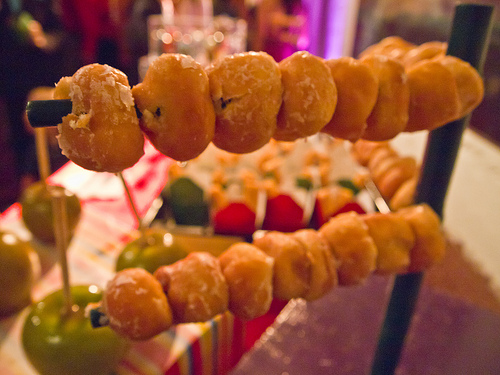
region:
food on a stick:
[21, 50, 493, 172]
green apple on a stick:
[15, 192, 146, 373]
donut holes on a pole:
[82, 207, 457, 352]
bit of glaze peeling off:
[111, 270, 141, 288]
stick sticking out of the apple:
[35, 134, 58, 189]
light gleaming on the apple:
[82, 281, 105, 294]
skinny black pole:
[357, 6, 499, 371]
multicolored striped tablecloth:
[2, 202, 235, 372]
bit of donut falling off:
[64, 107, 96, 138]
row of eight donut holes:
[33, 49, 482, 181]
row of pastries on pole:
[27, 47, 475, 167]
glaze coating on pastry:
[88, 80, 134, 141]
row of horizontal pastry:
[197, 228, 397, 315]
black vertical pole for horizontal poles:
[379, 33, 492, 327]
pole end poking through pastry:
[22, 78, 87, 141]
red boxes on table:
[213, 173, 320, 234]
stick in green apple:
[26, 216, 113, 363]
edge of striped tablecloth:
[185, 317, 253, 373]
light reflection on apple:
[155, 227, 177, 253]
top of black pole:
[445, 1, 497, 40]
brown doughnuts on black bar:
[49, 48, 494, 168]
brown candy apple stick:
[40, 195, 78, 290]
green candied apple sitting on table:
[30, 283, 110, 368]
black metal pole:
[420, 129, 467, 205]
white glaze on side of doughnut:
[101, 74, 136, 116]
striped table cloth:
[175, 323, 220, 362]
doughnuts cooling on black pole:
[41, 25, 481, 335]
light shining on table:
[89, 176, 122, 216]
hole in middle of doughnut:
[215, 82, 244, 121]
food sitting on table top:
[159, 156, 361, 225]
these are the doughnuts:
[71, 26, 466, 161]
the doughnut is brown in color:
[218, 53, 278, 134]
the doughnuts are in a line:
[73, 55, 383, 146]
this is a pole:
[423, 128, 461, 200]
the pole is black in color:
[413, 136, 465, 201]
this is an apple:
[31, 307, 83, 362]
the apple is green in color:
[37, 326, 90, 361]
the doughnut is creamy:
[70, 63, 127, 165]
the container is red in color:
[265, 197, 300, 227]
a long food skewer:
[30, 42, 495, 154]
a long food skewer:
[80, 202, 458, 344]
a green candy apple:
[19, 189, 131, 374]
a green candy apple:
[110, 177, 182, 277]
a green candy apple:
[23, 123, 81, 245]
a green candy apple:
[0, 232, 39, 312]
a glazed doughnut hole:
[48, 59, 138, 175]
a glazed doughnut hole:
[127, 44, 213, 161]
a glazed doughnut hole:
[213, 52, 278, 157]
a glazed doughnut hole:
[273, 48, 334, 138]